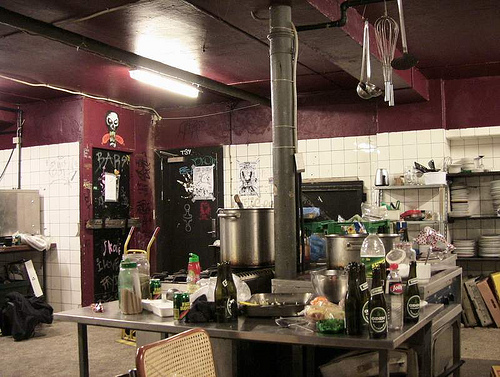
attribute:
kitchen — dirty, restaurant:
[3, 113, 407, 373]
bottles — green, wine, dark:
[309, 258, 410, 327]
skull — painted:
[77, 96, 170, 160]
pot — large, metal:
[215, 216, 285, 280]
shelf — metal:
[423, 163, 499, 232]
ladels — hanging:
[349, 11, 416, 139]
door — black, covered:
[84, 149, 220, 240]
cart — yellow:
[90, 323, 171, 359]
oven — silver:
[412, 267, 471, 337]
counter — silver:
[185, 293, 328, 368]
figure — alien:
[94, 182, 180, 282]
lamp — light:
[111, 57, 221, 113]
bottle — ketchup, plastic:
[174, 241, 220, 287]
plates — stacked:
[444, 194, 491, 255]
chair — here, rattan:
[122, 321, 237, 365]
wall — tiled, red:
[39, 147, 98, 220]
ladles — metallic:
[313, 21, 396, 135]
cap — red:
[384, 257, 419, 283]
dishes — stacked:
[419, 153, 495, 175]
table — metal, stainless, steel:
[59, 303, 131, 325]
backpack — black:
[7, 286, 58, 342]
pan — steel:
[228, 278, 309, 322]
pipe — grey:
[243, 63, 323, 254]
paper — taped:
[101, 168, 135, 212]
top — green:
[177, 244, 204, 274]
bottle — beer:
[337, 242, 390, 341]